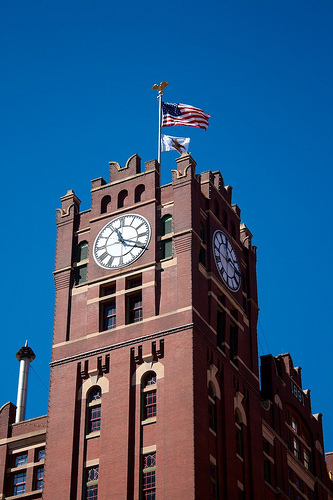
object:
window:
[34, 464, 46, 491]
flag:
[159, 133, 191, 155]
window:
[139, 368, 157, 422]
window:
[84, 383, 103, 434]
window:
[125, 287, 144, 325]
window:
[98, 297, 117, 331]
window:
[217, 308, 225, 352]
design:
[48, 160, 261, 419]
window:
[82, 464, 99, 499]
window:
[157, 212, 174, 263]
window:
[74, 238, 89, 286]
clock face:
[93, 215, 149, 268]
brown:
[155, 268, 180, 308]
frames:
[50, 191, 193, 367]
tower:
[48, 149, 259, 498]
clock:
[91, 213, 152, 273]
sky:
[0, 1, 333, 360]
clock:
[211, 227, 242, 294]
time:
[109, 218, 147, 253]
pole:
[156, 94, 163, 166]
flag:
[152, 95, 220, 128]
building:
[0, 149, 333, 498]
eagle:
[151, 79, 170, 97]